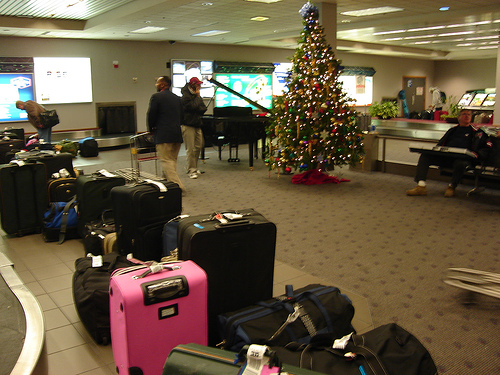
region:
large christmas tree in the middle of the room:
[267, 8, 365, 183]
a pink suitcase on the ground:
[110, 254, 207, 373]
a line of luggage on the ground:
[1, 127, 438, 373]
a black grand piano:
[204, 79, 271, 166]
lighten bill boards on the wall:
[0, 56, 373, 120]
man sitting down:
[408, 110, 478, 200]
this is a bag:
[285, 328, 430, 363]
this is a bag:
[228, 282, 349, 354]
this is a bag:
[156, 323, 311, 373]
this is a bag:
[102, 253, 207, 370]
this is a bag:
[165, 198, 296, 325]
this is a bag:
[52, 229, 139, 326]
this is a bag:
[96, 151, 182, 250]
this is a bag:
[42, 168, 85, 238]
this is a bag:
[5, 150, 70, 245]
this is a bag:
[69, 122, 111, 168]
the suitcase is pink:
[112, 269, 212, 371]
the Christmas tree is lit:
[280, 43, 357, 166]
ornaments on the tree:
[290, 62, 345, 126]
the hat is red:
[189, 76, 201, 83]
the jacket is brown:
[25, 100, 45, 118]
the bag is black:
[43, 112, 60, 128]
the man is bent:
[15, 100, 56, 137]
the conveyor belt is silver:
[56, 128, 139, 142]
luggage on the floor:
[19, 192, 433, 374]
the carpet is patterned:
[269, 193, 474, 280]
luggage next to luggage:
[3, 155, 47, 237]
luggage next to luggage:
[46, 197, 81, 240]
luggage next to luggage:
[48, 173, 77, 206]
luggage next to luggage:
[77, 170, 125, 250]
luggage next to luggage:
[110, 181, 181, 262]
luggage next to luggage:
[161, 206, 277, 347]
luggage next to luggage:
[73, 249, 143, 346]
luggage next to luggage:
[107, 259, 204, 374]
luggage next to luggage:
[212, 282, 355, 353]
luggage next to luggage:
[164, 338, 327, 373]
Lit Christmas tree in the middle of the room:
[265, 0, 375, 185]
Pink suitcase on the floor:
[111, 258, 209, 373]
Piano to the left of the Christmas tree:
[193, 73, 272, 166]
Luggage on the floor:
[0, 133, 442, 374]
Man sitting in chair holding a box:
[402, 104, 481, 200]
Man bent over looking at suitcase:
[13, 96, 60, 146]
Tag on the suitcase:
[240, 344, 269, 374]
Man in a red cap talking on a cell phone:
[179, 75, 206, 183]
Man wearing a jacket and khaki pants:
[145, 70, 185, 194]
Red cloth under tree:
[286, 166, 349, 187]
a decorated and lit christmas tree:
[266, 1, 366, 175]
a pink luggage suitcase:
[107, 261, 208, 373]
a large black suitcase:
[179, 208, 276, 346]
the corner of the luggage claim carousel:
[2, 249, 47, 374]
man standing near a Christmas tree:
[180, 1, 367, 193]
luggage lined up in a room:
[3, 126, 439, 373]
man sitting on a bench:
[405, 107, 499, 197]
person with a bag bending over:
[12, 98, 62, 145]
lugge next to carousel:
[108, 260, 207, 374]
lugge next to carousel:
[178, 206, 275, 347]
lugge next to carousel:
[218, 281, 358, 351]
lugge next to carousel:
[164, 342, 326, 374]